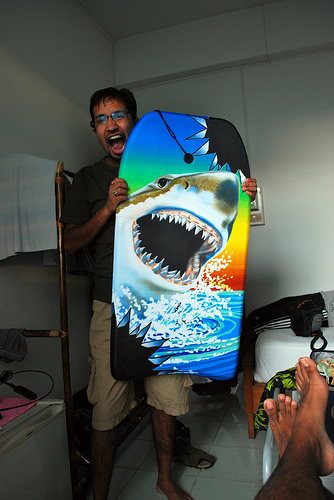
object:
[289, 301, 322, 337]
camera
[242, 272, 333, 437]
bed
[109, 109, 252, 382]
board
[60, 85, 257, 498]
man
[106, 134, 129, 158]
mouth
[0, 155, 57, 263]
cloth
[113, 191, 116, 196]
ring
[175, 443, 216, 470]
sandal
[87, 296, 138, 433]
short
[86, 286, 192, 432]
pant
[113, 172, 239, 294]
shark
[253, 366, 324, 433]
pillow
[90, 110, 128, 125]
glass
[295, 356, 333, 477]
feet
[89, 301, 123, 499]
leg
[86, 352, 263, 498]
floor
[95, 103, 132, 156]
face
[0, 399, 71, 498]
fridge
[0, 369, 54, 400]
wire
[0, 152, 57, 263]
towel